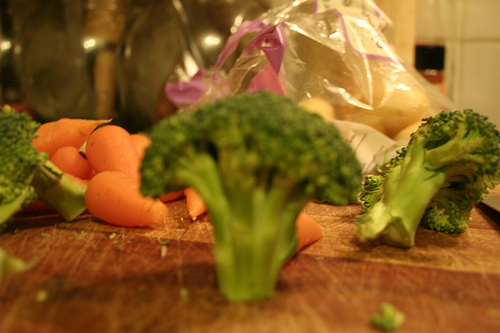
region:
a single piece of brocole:
[140, 96, 360, 303]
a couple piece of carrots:
[27, 113, 190, 228]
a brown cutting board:
[2, 151, 494, 329]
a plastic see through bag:
[170, 0, 476, 185]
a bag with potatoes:
[163, 1, 474, 188]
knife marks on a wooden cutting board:
[0, 183, 443, 328]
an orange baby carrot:
[91, 120, 145, 185]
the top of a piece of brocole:
[136, 90, 363, 200]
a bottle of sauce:
[408, 30, 455, 104]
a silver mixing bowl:
[111, 0, 275, 120]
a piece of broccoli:
[158, 99, 350, 306]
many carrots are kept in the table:
[41, 105, 158, 225]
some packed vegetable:
[218, 17, 432, 142]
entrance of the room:
[411, 31, 453, 98]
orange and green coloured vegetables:
[15, 95, 484, 318]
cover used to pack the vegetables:
[254, 11, 306, 84]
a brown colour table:
[56, 236, 186, 314]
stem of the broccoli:
[213, 208, 300, 313]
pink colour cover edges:
[224, 9, 282, 89]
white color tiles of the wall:
[469, 27, 494, 107]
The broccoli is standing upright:
[125, 83, 368, 300]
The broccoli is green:
[151, 97, 356, 302]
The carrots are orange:
[14, 98, 179, 238]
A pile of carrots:
[26, 98, 183, 238]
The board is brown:
[8, 177, 494, 323]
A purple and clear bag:
[175, 6, 438, 158]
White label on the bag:
[322, 98, 402, 170]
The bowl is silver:
[115, 2, 235, 129]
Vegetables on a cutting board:
[6, 89, 490, 301]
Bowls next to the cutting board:
[13, 9, 260, 131]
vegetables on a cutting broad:
[18, 35, 475, 331]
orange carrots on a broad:
[85, 126, 156, 222]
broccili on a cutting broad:
[133, 100, 349, 315]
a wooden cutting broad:
[35, 220, 192, 325]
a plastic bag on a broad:
[176, 0, 452, 85]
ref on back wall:
[418, 0, 494, 76]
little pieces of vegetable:
[370, 298, 411, 330]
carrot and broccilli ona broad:
[80, 95, 347, 310]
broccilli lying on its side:
[338, 93, 498, 265]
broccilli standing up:
[139, 69, 364, 307]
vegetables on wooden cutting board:
[12, 17, 485, 325]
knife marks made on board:
[65, 235, 440, 315]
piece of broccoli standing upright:
[137, 87, 362, 302]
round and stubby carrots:
[37, 120, 159, 230]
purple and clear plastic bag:
[170, 0, 440, 140]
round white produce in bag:
[297, 46, 422, 141]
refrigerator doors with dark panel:
[392, 5, 494, 105]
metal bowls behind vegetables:
[11, 10, 241, 115]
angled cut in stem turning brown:
[350, 200, 412, 250]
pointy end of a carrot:
[61, 115, 113, 127]